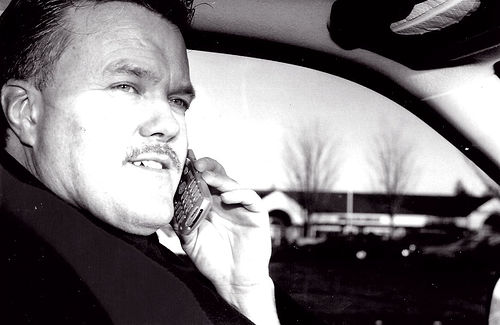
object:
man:
[0, 0, 281, 325]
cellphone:
[171, 149, 211, 236]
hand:
[179, 157, 272, 287]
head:
[1, 0, 195, 237]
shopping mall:
[254, 192, 500, 246]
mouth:
[128, 151, 174, 179]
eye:
[106, 83, 141, 97]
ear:
[0, 79, 41, 147]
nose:
[140, 96, 181, 143]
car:
[0, 0, 499, 324]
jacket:
[0, 148, 257, 324]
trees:
[285, 127, 417, 240]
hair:
[0, 1, 195, 84]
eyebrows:
[106, 61, 157, 83]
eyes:
[168, 93, 192, 113]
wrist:
[212, 269, 274, 307]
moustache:
[126, 144, 182, 172]